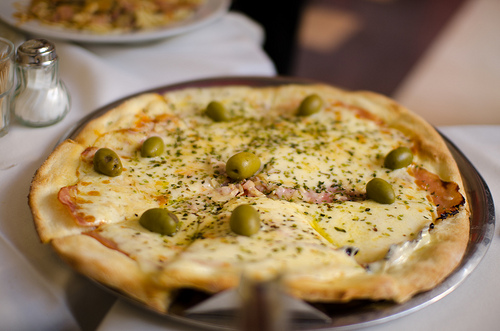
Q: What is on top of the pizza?
A: Melted cheese.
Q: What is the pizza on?
A: Pizza pan.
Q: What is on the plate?
A: Food.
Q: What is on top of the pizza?
A: Olives.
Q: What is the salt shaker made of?
A: Glass.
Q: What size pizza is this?
A: Personal.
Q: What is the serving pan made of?
A: Metal.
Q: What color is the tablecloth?
A: White.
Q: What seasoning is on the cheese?
A: Oregano.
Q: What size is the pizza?
A: Small.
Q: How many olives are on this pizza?
A: 9.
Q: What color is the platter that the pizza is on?
A: Silver.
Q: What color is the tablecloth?
A: White.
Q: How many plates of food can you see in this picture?
A: 2.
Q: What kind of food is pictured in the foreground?
A: Pizza.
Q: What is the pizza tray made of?
A: Metal.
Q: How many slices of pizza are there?
A: 8.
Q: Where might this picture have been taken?
A: Italian restaurant.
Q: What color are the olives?
A: Green.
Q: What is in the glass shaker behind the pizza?
A: Salt.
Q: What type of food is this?
A: Pizza.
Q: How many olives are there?
A: Nine.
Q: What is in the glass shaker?
A: Salt.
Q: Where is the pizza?
A: On the table.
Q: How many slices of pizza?
A: Eight.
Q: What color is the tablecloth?
A: White.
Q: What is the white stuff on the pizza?
A: Cheese.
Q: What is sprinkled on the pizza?
A: Herbs.